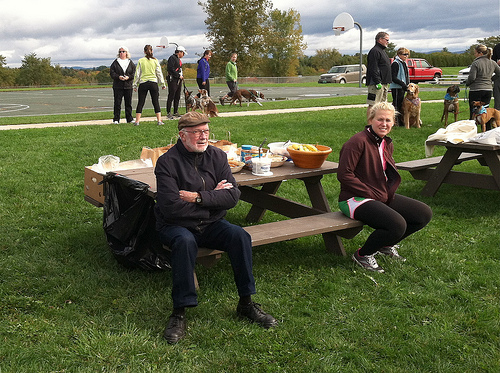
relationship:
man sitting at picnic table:
[153, 110, 277, 345] [103, 129, 355, 246]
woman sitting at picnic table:
[336, 101, 433, 273] [103, 129, 355, 246]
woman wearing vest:
[395, 45, 410, 125] [395, 60, 410, 90]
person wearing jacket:
[218, 47, 241, 105] [225, 60, 239, 81]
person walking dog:
[218, 47, 241, 105] [224, 90, 270, 104]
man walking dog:
[193, 46, 211, 95] [195, 87, 217, 115]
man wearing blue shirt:
[193, 46, 211, 95] [195, 53, 211, 82]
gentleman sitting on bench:
[104, 87, 267, 332] [82, 143, 362, 283]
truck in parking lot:
[405, 57, 442, 84] [2, 87, 369, 113]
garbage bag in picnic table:
[101, 169, 160, 275] [83, 137, 366, 290]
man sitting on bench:
[153, 110, 277, 345] [144, 204, 385, 304]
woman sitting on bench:
[336, 101, 433, 279] [144, 204, 385, 304]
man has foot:
[153, 110, 277, 345] [233, 297, 277, 327]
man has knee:
[153, 110, 277, 345] [203, 197, 263, 292]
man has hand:
[153, 110, 277, 345] [181, 187, 201, 204]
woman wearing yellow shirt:
[133, 43, 172, 130] [136, 53, 160, 82]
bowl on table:
[293, 155, 326, 166] [129, 165, 149, 180]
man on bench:
[145, 99, 282, 334] [179, 189, 436, 290]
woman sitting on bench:
[336, 101, 433, 279] [176, 202, 376, 258]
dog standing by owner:
[400, 83, 422, 129] [385, 44, 416, 134]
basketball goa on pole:
[325, 9, 372, 95] [349, 21, 369, 75]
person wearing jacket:
[219, 51, 239, 106] [225, 56, 240, 81]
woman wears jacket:
[336, 101, 433, 279] [334, 130, 407, 211]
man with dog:
[166, 42, 188, 121] [184, 87, 200, 110]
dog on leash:
[184, 87, 200, 110] [180, 77, 190, 104]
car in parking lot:
[317, 61, 367, 86] [265, 81, 373, 90]